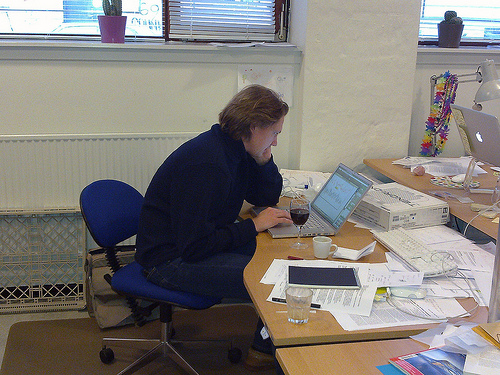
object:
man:
[119, 73, 282, 365]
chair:
[78, 172, 250, 373]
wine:
[287, 206, 310, 227]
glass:
[288, 195, 311, 252]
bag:
[77, 243, 162, 333]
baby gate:
[2, 208, 90, 314]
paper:
[420, 227, 491, 281]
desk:
[225, 164, 499, 352]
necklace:
[426, 73, 456, 161]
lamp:
[419, 59, 499, 157]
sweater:
[137, 125, 282, 271]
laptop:
[247, 160, 373, 241]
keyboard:
[369, 226, 459, 281]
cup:
[310, 235, 338, 261]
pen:
[271, 296, 323, 311]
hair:
[217, 82, 288, 139]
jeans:
[133, 247, 280, 350]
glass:
[282, 285, 316, 329]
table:
[355, 139, 498, 243]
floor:
[3, 292, 286, 374]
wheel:
[92, 345, 116, 369]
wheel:
[223, 348, 246, 365]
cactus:
[101, 1, 126, 17]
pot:
[97, 16, 130, 44]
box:
[353, 180, 455, 231]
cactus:
[439, 8, 466, 26]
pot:
[433, 22, 464, 48]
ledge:
[408, 42, 499, 63]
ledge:
[1, 38, 300, 66]